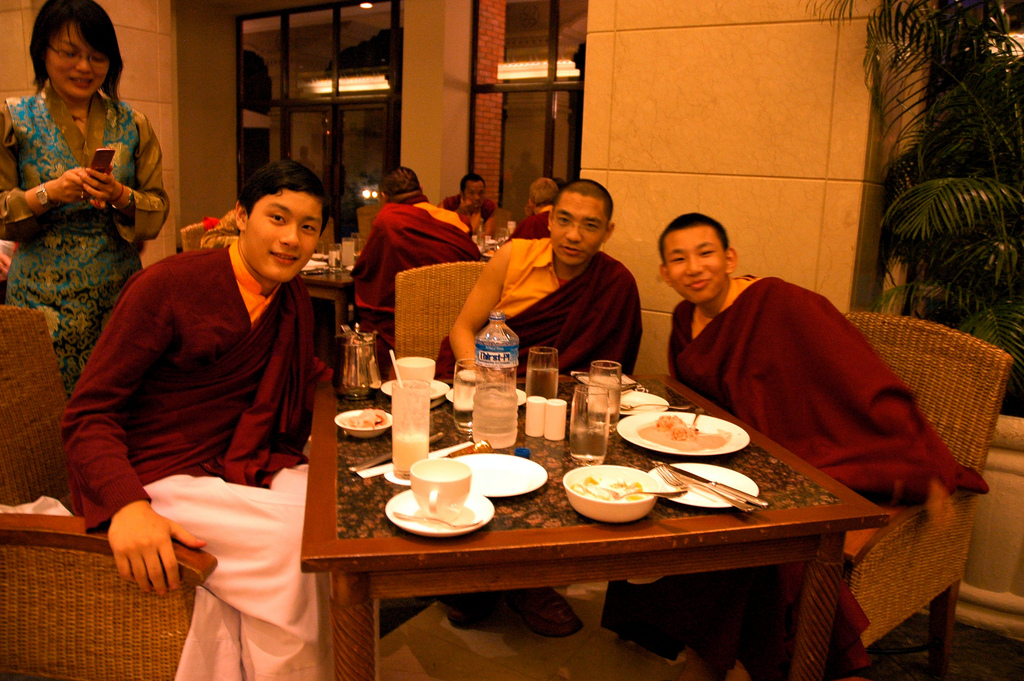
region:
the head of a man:
[215, 146, 313, 290]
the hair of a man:
[244, 151, 325, 199]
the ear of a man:
[224, 198, 266, 236]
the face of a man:
[260, 193, 311, 276]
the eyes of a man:
[271, 203, 320, 246]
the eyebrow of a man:
[260, 193, 325, 220]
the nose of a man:
[274, 224, 309, 256]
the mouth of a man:
[262, 247, 307, 267]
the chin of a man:
[262, 262, 300, 286]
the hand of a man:
[92, 473, 213, 607]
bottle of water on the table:
[471, 300, 528, 450]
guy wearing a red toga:
[645, 192, 908, 465]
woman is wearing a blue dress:
[13, 2, 159, 277]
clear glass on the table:
[563, 379, 621, 462]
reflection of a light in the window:
[294, 56, 386, 99]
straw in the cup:
[380, 345, 407, 391]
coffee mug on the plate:
[405, 456, 470, 513]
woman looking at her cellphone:
[7, 6, 150, 225]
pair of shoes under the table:
[427, 590, 590, 639]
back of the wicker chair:
[940, 351, 995, 419]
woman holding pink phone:
[0, 0, 175, 392]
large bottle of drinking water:
[465, 304, 529, 454]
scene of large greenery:
[846, 0, 1021, 426]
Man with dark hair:
[113, 164, 366, 522]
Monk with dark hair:
[119, 161, 350, 577]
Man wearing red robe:
[89, 143, 375, 630]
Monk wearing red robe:
[92, 162, 348, 599]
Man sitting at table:
[105, 156, 371, 675]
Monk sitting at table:
[55, 141, 373, 626]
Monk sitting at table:
[633, 207, 960, 550]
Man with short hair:
[643, 201, 941, 527]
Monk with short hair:
[480, 168, 649, 407]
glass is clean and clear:
[470, 90, 544, 230]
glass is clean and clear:
[551, 90, 580, 195]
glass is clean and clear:
[554, 6, 586, 80]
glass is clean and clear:
[472, 0, 550, 77]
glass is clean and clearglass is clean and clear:
[286, 8, 338, 98]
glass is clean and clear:
[290, 11, 330, 98]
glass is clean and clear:
[238, 11, 278, 98]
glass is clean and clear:
[239, 104, 281, 200]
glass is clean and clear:
[287, 109, 329, 199]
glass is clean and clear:
[340, 99, 397, 235]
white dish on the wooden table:
[381, 476, 493, 546]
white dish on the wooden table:
[425, 446, 542, 503]